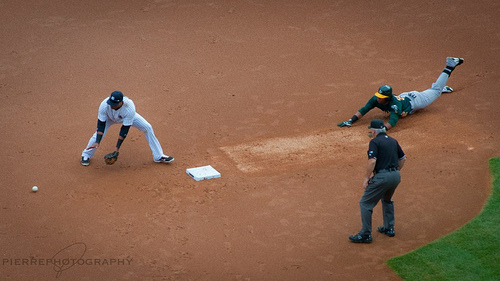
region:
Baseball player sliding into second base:
[332, 49, 465, 137]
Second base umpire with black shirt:
[343, 115, 410, 245]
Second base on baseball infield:
[180, 152, 232, 193]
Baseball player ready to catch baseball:
[24, 85, 179, 209]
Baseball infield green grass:
[388, 155, 495, 278]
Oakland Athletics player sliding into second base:
[334, 51, 469, 136]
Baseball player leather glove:
[99, 147, 122, 170]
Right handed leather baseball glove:
[100, 145, 124, 168]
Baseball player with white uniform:
[75, 86, 177, 175]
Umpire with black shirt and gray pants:
[349, 117, 406, 249]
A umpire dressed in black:
[363, 120, 414, 198]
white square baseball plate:
[179, 152, 240, 216]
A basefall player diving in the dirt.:
[359, 56, 486, 125]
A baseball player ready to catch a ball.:
[83, 64, 180, 174]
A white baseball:
[18, 175, 85, 219]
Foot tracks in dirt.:
[249, 210, 306, 266]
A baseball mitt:
[98, 147, 131, 174]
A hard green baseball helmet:
[366, 80, 401, 107]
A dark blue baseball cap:
[99, 87, 133, 116]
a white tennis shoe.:
[448, 50, 470, 74]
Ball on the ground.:
[12, 175, 52, 206]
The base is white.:
[174, 145, 229, 195]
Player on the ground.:
[332, 46, 473, 125]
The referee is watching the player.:
[343, 110, 433, 247]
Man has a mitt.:
[77, 88, 169, 165]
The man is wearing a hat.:
[93, 80, 124, 121]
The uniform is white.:
[83, 95, 148, 171]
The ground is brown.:
[26, 12, 441, 264]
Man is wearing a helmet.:
[367, 73, 402, 104]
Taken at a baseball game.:
[8, 7, 498, 277]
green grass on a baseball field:
[382, 155, 498, 279]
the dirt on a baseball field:
[0, 0, 497, 279]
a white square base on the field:
[184, 160, 220, 190]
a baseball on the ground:
[25, 182, 41, 197]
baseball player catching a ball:
[72, 85, 177, 173]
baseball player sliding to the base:
[335, 48, 467, 148]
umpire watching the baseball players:
[342, 116, 410, 248]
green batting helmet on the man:
[367, 81, 397, 103]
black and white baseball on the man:
[105, 88, 125, 108]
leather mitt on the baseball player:
[100, 148, 121, 167]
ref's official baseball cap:
[362, 119, 385, 129]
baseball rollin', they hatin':
[27, 182, 40, 197]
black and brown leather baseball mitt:
[102, 149, 118, 167]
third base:
[180, 163, 220, 184]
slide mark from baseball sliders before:
[220, 127, 359, 175]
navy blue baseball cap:
[105, 91, 124, 108]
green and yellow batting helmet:
[372, 84, 394, 100]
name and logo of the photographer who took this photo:
[0, 239, 135, 279]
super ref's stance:
[364, 130, 406, 175]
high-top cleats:
[442, 52, 464, 71]